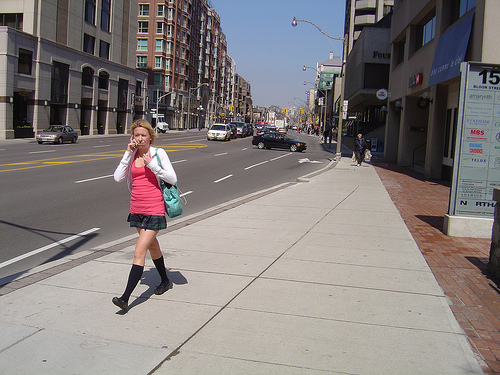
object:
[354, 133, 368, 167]
person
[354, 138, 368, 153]
jacket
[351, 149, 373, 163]
bags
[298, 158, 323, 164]
traffic arrows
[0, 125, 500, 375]
road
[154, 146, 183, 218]
bag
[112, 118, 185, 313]
woman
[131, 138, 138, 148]
cellphone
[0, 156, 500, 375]
sidewalk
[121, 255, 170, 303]
socks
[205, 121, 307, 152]
vehicles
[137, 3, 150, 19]
window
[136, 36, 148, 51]
window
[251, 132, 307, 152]
car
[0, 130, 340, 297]
street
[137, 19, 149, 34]
window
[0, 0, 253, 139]
building